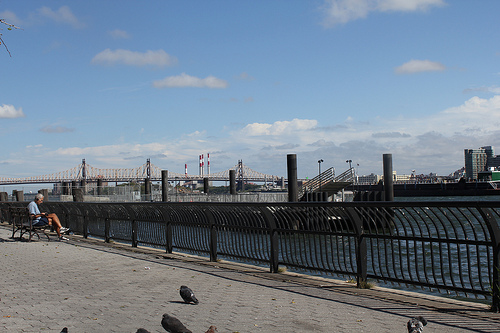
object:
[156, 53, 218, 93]
clouds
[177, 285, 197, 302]
bird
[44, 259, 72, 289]
sidewalk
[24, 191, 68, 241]
man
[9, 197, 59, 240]
bench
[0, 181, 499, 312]
barge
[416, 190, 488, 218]
water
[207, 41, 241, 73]
sky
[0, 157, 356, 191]
bridge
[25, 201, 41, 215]
shirt